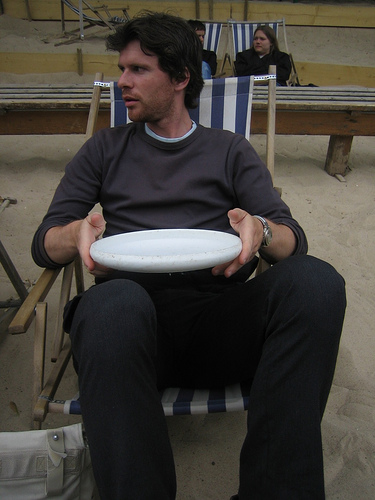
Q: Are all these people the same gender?
A: No, they are both male and female.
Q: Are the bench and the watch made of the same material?
A: No, the bench is made of wood and the watch is made of metal.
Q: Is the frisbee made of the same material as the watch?
A: No, the frisbee is made of plastic and the watch is made of metal.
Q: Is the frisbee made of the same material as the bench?
A: No, the frisbee is made of plastic and the bench is made of wood.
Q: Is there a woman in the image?
A: Yes, there is a woman.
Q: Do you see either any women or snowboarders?
A: Yes, there is a woman.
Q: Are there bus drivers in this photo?
A: No, there are no bus drivers.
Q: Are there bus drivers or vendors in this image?
A: No, there are no bus drivers or vendors.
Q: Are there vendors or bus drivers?
A: No, there are no bus drivers or vendors.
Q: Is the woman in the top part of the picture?
A: Yes, the woman is in the top of the image.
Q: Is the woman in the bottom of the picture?
A: No, the woman is in the top of the image.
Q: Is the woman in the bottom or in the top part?
A: The woman is in the top of the image.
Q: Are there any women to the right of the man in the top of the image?
A: Yes, there is a woman to the right of the man.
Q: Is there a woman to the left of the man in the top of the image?
A: No, the woman is to the right of the man.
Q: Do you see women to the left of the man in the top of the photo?
A: No, the woman is to the right of the man.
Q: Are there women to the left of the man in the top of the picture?
A: No, the woman is to the right of the man.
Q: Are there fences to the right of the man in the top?
A: No, there is a woman to the right of the man.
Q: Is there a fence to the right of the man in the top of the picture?
A: No, there is a woman to the right of the man.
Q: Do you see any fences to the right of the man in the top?
A: No, there is a woman to the right of the man.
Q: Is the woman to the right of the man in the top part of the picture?
A: Yes, the woman is to the right of the man.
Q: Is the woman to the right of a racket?
A: No, the woman is to the right of the man.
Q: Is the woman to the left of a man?
A: No, the woman is to the right of a man.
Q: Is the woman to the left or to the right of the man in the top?
A: The woman is to the right of the man.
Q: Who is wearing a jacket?
A: The woman is wearing a jacket.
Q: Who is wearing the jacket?
A: The woman is wearing a jacket.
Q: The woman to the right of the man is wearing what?
A: The woman is wearing a jacket.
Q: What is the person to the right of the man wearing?
A: The woman is wearing a jacket.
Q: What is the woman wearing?
A: The woman is wearing a jacket.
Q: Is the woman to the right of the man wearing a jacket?
A: Yes, the woman is wearing a jacket.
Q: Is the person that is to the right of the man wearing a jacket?
A: Yes, the woman is wearing a jacket.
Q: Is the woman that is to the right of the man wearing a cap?
A: No, the woman is wearing a jacket.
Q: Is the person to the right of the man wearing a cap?
A: No, the woman is wearing a jacket.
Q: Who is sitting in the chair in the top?
A: The woman is sitting in the chair.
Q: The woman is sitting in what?
A: The woman is sitting in the chair.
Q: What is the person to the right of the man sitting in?
A: The woman is sitting in the chair.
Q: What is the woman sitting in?
A: The woman is sitting in the chair.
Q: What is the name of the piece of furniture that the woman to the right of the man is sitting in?
A: The piece of furniture is a chair.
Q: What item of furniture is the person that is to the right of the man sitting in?
A: The woman is sitting in the chair.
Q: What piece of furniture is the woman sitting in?
A: The woman is sitting in the chair.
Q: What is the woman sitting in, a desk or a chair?
A: The woman is sitting in a chair.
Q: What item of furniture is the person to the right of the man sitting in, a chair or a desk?
A: The woman is sitting in a chair.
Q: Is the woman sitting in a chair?
A: Yes, the woman is sitting in a chair.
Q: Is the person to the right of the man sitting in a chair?
A: Yes, the woman is sitting in a chair.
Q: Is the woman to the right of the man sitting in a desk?
A: No, the woman is sitting in a chair.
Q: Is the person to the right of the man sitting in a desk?
A: No, the woman is sitting in a chair.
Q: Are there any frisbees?
A: Yes, there is a frisbee.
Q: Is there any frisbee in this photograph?
A: Yes, there is a frisbee.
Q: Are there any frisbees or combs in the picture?
A: Yes, there is a frisbee.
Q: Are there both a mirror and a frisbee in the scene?
A: No, there is a frisbee but no mirrors.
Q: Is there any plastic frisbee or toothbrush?
A: Yes, there is a plastic frisbee.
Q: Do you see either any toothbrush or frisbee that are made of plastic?
A: Yes, the frisbee is made of plastic.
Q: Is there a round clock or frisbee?
A: Yes, there is a round frisbee.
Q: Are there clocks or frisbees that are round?
A: Yes, the frisbee is round.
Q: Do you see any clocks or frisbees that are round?
A: Yes, the frisbee is round.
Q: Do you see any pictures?
A: No, there are no pictures.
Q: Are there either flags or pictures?
A: No, there are no pictures or flags.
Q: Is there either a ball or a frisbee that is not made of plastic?
A: No, there is a frisbee but it is made of plastic.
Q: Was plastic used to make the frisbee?
A: Yes, the frisbee is made of plastic.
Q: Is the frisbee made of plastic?
A: Yes, the frisbee is made of plastic.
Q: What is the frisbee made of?
A: The frisbee is made of plastic.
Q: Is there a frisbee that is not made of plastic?
A: No, there is a frisbee but it is made of plastic.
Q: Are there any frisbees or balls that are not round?
A: No, there is a frisbee but it is round.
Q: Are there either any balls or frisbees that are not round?
A: No, there is a frisbee but it is round.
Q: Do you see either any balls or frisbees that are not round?
A: No, there is a frisbee but it is round.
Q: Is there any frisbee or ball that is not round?
A: No, there is a frisbee but it is round.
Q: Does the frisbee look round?
A: Yes, the frisbee is round.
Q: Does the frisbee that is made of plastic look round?
A: Yes, the frisbee is round.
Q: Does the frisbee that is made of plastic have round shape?
A: Yes, the frisbee is round.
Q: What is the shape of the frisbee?
A: The frisbee is round.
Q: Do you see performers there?
A: No, there are no performers.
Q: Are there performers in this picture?
A: No, there are no performers.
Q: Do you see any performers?
A: No, there are no performers.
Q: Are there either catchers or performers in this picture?
A: No, there are no performers or catchers.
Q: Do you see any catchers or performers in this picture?
A: No, there are no performers or catchers.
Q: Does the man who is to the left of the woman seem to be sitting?
A: Yes, the man is sitting.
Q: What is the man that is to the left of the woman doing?
A: The man is sitting.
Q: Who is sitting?
A: The man is sitting.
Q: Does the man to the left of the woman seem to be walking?
A: No, the man is sitting.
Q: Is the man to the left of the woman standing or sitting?
A: The man is sitting.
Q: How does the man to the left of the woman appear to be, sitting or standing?
A: The man is sitting.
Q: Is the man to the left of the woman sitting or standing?
A: The man is sitting.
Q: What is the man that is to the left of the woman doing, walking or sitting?
A: The man is sitting.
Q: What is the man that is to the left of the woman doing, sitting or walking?
A: The man is sitting.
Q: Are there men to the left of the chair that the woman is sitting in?
A: Yes, there is a man to the left of the chair.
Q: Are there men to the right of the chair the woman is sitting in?
A: No, the man is to the left of the chair.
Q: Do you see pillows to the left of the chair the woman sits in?
A: No, there is a man to the left of the chair.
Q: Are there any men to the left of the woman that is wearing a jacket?
A: Yes, there is a man to the left of the woman.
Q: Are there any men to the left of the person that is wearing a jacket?
A: Yes, there is a man to the left of the woman.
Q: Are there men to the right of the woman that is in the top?
A: No, the man is to the left of the woman.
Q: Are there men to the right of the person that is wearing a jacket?
A: No, the man is to the left of the woman.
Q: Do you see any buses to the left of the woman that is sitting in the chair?
A: No, there is a man to the left of the woman.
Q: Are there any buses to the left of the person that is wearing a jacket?
A: No, there is a man to the left of the woman.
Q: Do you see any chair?
A: Yes, there is a chair.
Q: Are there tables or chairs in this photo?
A: Yes, there is a chair.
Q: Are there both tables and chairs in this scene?
A: No, there is a chair but no tables.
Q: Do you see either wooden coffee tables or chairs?
A: Yes, there is a wood chair.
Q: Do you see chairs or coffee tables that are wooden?
A: Yes, the chair is wooden.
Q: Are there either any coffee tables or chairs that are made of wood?
A: Yes, the chair is made of wood.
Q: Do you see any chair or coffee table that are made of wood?
A: Yes, the chair is made of wood.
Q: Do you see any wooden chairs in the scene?
A: Yes, there is a wood chair.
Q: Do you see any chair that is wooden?
A: Yes, there is a chair that is wooden.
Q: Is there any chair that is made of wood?
A: Yes, there is a chair that is made of wood.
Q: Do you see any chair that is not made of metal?
A: Yes, there is a chair that is made of wood.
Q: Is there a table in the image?
A: No, there are no tables.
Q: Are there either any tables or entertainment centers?
A: No, there are no tables or entertainment centers.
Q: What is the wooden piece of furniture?
A: The piece of furniture is a chair.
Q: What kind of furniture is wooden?
A: The furniture is a chair.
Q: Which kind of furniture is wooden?
A: The furniture is a chair.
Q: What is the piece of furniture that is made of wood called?
A: The piece of furniture is a chair.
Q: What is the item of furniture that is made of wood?
A: The piece of furniture is a chair.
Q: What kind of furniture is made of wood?
A: The furniture is a chair.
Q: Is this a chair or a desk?
A: This is a chair.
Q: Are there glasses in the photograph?
A: No, there are no glasses.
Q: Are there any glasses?
A: No, there are no glasses.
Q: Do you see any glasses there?
A: No, there are no glasses.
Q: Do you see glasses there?
A: No, there are no glasses.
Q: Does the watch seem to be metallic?
A: Yes, the watch is metallic.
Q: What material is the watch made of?
A: The watch is made of metal.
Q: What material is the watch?
A: The watch is made of metal.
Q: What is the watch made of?
A: The watch is made of metal.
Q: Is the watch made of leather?
A: No, the watch is made of metal.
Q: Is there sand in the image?
A: Yes, there is sand.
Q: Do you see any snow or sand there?
A: Yes, there is sand.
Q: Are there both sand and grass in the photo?
A: No, there is sand but no grass.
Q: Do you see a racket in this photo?
A: No, there are no rackets.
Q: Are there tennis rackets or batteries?
A: No, there are no tennis rackets or batteries.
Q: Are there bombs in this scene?
A: No, there are no bombs.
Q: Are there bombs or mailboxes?
A: No, there are no bombs or mailboxes.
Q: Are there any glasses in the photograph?
A: No, there are no glasses.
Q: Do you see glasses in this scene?
A: No, there are no glasses.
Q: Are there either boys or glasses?
A: No, there are no glasses or boys.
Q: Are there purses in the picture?
A: Yes, there is a purse.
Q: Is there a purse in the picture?
A: Yes, there is a purse.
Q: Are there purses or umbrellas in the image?
A: Yes, there is a purse.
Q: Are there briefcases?
A: No, there are no briefcases.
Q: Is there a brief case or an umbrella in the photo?
A: No, there are no briefcases or umbrellas.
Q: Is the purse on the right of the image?
A: No, the purse is on the left of the image.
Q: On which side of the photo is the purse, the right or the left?
A: The purse is on the left of the image.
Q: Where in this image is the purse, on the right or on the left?
A: The purse is on the left of the image.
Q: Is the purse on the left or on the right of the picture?
A: The purse is on the left of the image.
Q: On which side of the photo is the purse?
A: The purse is on the left of the image.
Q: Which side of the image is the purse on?
A: The purse is on the left of the image.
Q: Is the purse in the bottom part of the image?
A: Yes, the purse is in the bottom of the image.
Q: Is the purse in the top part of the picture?
A: No, the purse is in the bottom of the image.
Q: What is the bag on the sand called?
A: The bag is a purse.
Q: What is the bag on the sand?
A: The bag is a purse.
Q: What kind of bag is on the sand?
A: The bag is a purse.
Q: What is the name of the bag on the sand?
A: The bag is a purse.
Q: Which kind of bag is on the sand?
A: The bag is a purse.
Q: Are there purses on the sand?
A: Yes, there is a purse on the sand.